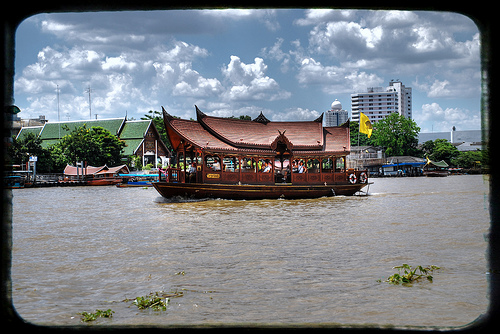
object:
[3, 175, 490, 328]
water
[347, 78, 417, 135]
building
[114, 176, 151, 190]
boat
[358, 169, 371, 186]
life rings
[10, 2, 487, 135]
clouds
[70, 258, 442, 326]
plants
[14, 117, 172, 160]
roof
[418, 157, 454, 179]
boat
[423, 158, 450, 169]
roof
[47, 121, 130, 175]
tree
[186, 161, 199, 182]
person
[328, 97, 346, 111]
top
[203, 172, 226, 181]
plaque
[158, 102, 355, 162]
roof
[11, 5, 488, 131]
sky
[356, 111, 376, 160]
flag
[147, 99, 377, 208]
boat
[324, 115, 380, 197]
back